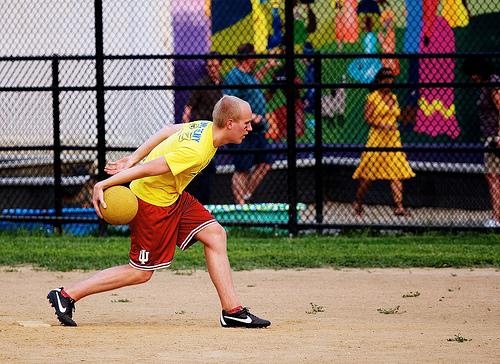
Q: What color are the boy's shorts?
A: Red.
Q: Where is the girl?
A: Behind the fence.